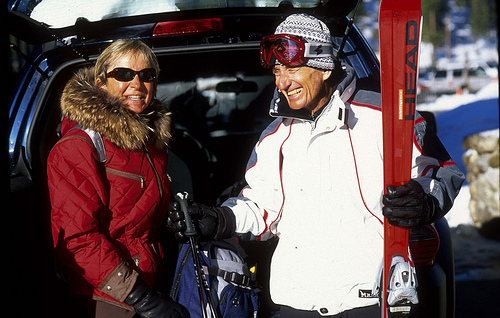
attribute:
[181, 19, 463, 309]
jacket — white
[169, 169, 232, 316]
poles — ski 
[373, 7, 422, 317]
skis — red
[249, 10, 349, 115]
head — around 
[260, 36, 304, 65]
goggles — red 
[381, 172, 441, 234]
glove —  black 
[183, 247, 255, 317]
backpack — Blue  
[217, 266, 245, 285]
buckle —  black  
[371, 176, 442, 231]
gloves —  black bulky 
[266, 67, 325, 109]
smile —  big 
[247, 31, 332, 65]
ski mask — red 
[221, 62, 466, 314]
jacket — red, white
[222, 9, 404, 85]
knit hat — grey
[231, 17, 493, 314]
man coat —  red , white 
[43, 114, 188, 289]
winter jacket — red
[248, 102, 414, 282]
jacket — white, red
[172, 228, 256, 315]
backpack — grey, blue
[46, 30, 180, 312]
woman — blond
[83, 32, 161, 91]
hair — short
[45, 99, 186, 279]
red coat — furry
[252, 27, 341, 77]
goggles — red, grey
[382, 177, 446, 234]
glove — black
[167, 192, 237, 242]
glove — black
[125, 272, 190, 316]
glove — black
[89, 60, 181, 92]
glasses — pair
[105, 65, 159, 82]
sunglasses — black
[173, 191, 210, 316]
ski pole — metal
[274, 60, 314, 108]
face — his 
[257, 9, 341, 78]
hat — grey 